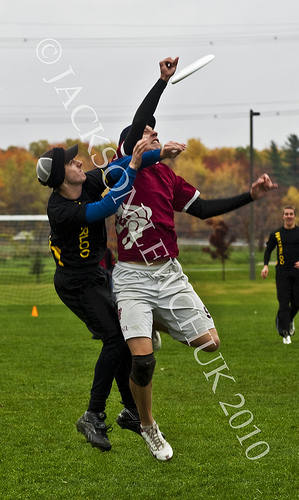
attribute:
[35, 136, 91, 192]
cap — baseball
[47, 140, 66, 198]
band — black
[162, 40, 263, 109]
frisbee — white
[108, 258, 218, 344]
shorts — gray, sports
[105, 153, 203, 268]
shirt — burgundy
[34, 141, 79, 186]
cap — black, white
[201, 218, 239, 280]
tree — small, red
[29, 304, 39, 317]
cone — orange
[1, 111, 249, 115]
electric line — black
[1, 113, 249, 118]
electric line — black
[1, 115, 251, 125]
electric line — black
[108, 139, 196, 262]
color — vivid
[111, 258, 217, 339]
color — vivid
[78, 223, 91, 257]
color — vivid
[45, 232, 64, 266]
color — vivid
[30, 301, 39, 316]
color — vivid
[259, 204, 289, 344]
person — running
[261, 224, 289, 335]
clothing — black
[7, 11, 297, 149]
sky — daytime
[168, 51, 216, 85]
frisbee —  white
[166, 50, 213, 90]
frisbee — white, round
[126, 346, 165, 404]
pad — black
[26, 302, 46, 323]
cone — orange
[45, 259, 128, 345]
pants — black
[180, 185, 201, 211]
trim — white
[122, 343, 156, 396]
brace — black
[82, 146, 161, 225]
sleeves — blue, shirt